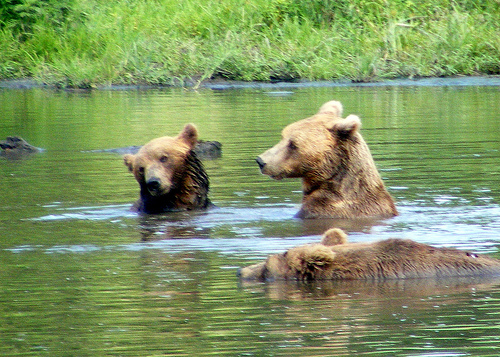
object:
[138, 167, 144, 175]
eyes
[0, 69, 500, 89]
river bank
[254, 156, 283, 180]
mouth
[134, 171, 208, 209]
neck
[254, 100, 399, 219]
bear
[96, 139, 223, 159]
rock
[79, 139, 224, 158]
wood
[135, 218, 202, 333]
reflection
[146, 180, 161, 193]
nose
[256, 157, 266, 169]
nose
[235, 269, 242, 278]
nose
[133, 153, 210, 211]
fur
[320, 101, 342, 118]
ears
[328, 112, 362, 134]
ears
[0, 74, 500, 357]
river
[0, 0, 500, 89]
grass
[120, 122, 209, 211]
bear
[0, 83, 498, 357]
water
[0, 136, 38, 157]
rock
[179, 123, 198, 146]
ear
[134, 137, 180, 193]
face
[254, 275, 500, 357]
reflection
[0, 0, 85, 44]
leaves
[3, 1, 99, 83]
tree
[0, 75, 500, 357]
lake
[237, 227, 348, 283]
head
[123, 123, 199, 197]
head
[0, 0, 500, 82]
foilage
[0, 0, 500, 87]
shrubbery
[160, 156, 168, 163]
eye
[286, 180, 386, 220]
shoulder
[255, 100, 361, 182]
head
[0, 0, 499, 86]
bank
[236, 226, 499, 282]
bear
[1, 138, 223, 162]
drift wood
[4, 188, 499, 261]
sunlight